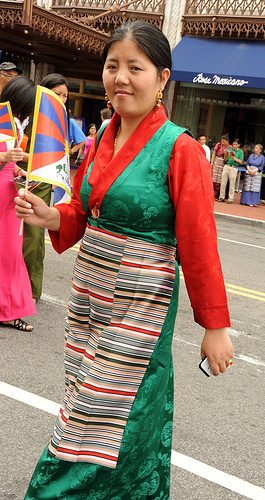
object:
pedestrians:
[193, 133, 264, 207]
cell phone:
[199, 356, 213, 377]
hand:
[198, 326, 233, 375]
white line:
[0, 380, 65, 419]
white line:
[170, 448, 265, 499]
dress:
[240, 153, 265, 206]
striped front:
[75, 128, 184, 205]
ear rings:
[155, 90, 163, 114]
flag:
[18, 83, 71, 238]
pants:
[219, 164, 238, 201]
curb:
[213, 211, 262, 229]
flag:
[0, 102, 19, 155]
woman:
[37, 73, 71, 105]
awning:
[168, 33, 265, 91]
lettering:
[193, 72, 249, 87]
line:
[225, 280, 265, 303]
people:
[240, 142, 264, 206]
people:
[217, 139, 244, 205]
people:
[210, 133, 231, 200]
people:
[196, 135, 209, 166]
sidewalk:
[211, 191, 264, 221]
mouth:
[114, 89, 133, 97]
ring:
[227, 359, 234, 367]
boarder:
[0, 73, 37, 331]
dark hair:
[98, 21, 173, 77]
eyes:
[107, 65, 141, 70]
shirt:
[74, 95, 211, 344]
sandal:
[0, 317, 34, 333]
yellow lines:
[223, 280, 264, 303]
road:
[211, 212, 264, 289]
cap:
[0, 62, 24, 78]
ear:
[160, 68, 171, 92]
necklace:
[114, 124, 122, 156]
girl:
[14, 17, 234, 498]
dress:
[22, 103, 231, 498]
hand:
[14, 186, 53, 230]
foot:
[2, 316, 31, 328]